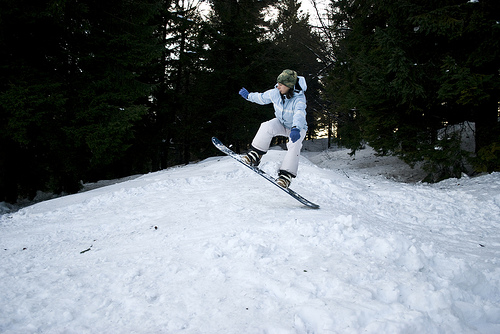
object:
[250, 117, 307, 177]
pants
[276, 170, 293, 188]
shoe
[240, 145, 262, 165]
shoe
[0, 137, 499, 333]
ski slope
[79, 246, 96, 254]
twigs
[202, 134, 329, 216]
snowboard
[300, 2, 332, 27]
cloudy sky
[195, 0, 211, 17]
cloudy sky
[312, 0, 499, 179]
tree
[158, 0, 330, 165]
tree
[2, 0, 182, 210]
tree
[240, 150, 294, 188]
boots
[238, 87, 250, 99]
glove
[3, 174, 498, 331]
snow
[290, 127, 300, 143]
glove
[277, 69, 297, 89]
beanie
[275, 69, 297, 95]
head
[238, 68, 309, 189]
girl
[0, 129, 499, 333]
hill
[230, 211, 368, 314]
marks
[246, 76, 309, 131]
coat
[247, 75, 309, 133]
hoodie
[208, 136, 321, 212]
board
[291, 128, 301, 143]
hand